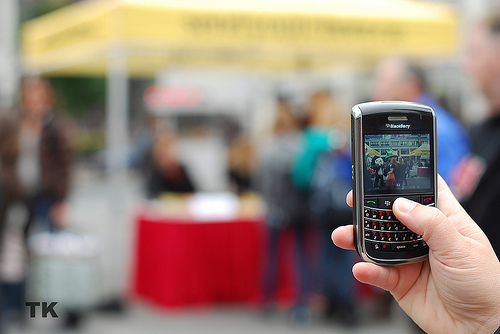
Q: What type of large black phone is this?
A: Blackberry.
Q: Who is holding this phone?
A: The man.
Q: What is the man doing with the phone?
A: Taking a picture.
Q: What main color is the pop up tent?
A: Yellow.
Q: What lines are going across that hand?
A: Wrinkles.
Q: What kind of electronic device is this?
A: Cell phone.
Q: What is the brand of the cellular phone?
A: Blackberry.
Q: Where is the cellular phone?
A: In a person's hand.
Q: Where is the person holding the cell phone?
A: In the air.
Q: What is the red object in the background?
A: Red tablecloth.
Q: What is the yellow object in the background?
A: Yellow tent on shopping display.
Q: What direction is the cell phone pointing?
A: Left.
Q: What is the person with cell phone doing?
A: Taking a photo.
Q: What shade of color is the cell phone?
A: Black and silver.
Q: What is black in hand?
A: Cell phone.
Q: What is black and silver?
A: Blackberry with keypad.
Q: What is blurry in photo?
A: Red and white cooler.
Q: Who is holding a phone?
A: A white hand.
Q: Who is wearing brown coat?
A: Blurry bystander.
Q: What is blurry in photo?
A: Line of people.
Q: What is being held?
A: A cell phone.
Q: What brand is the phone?
A: Blackberry.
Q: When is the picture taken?
A: Daytime.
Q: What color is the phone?
A: Black.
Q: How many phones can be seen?
A: 1.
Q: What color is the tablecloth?
A: Red.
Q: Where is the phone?
A: In a person's hand.